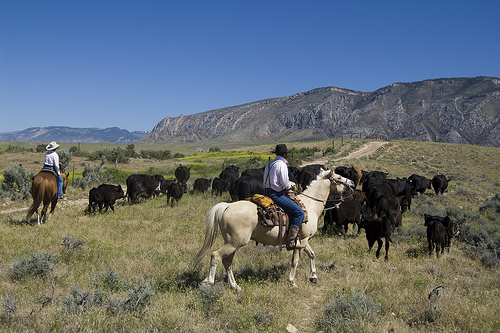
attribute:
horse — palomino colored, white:
[190, 163, 360, 299]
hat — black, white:
[270, 139, 290, 160]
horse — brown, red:
[27, 165, 75, 229]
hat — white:
[45, 136, 59, 155]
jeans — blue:
[270, 187, 306, 228]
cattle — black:
[88, 160, 462, 258]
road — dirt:
[11, 180, 164, 218]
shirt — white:
[261, 153, 295, 197]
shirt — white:
[43, 150, 62, 170]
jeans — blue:
[53, 172, 68, 203]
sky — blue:
[72, 16, 458, 63]